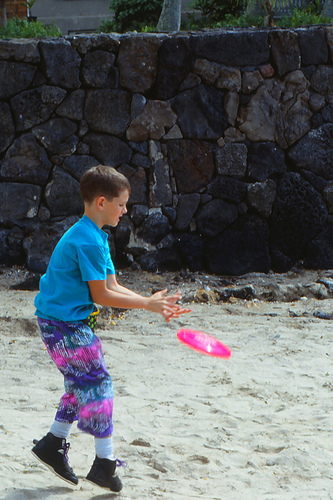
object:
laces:
[62, 439, 72, 459]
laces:
[113, 458, 122, 467]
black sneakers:
[85, 451, 121, 492]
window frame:
[63, 26, 99, 36]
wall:
[184, 23, 301, 242]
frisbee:
[177, 328, 232, 359]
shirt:
[32, 215, 115, 327]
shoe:
[29, 430, 79, 485]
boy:
[28, 153, 192, 495]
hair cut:
[78, 164, 132, 204]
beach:
[9, 279, 331, 483]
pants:
[36, 318, 114, 438]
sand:
[0, 289, 332, 499]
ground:
[0, 270, 332, 498]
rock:
[216, 140, 245, 179]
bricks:
[122, 82, 226, 141]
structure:
[134, 53, 296, 248]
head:
[79, 165, 132, 228]